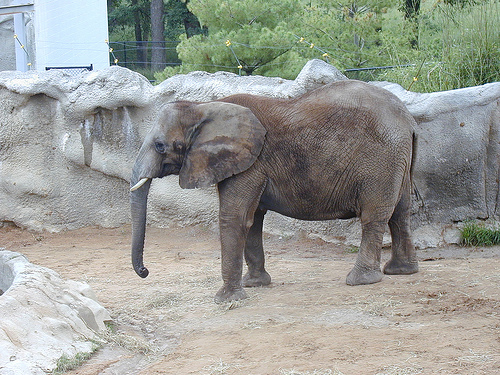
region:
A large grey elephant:
[117, 85, 427, 298]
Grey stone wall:
[0, 62, 497, 261]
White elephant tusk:
[116, 162, 161, 209]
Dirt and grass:
[30, 232, 497, 372]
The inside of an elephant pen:
[2, 65, 494, 373]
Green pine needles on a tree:
[152, 0, 339, 76]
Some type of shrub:
[385, 0, 498, 80]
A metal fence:
[346, 65, 415, 78]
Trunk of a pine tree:
[132, 0, 174, 71]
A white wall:
[20, 0, 112, 65]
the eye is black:
[149, 144, 179, 156]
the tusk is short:
[128, 176, 160, 195]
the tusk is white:
[126, 163, 153, 197]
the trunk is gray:
[125, 175, 172, 288]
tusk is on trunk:
[125, 165, 165, 277]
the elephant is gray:
[174, 102, 426, 292]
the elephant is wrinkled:
[247, 105, 392, 209]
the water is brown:
[155, 268, 485, 350]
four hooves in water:
[209, 259, 436, 316]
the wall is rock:
[2, 79, 297, 230]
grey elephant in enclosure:
[120, 80, 424, 290]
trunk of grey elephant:
[117, 155, 159, 278]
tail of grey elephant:
[401, 125, 432, 220]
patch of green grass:
[463, 225, 495, 247]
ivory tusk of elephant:
[124, 177, 152, 189]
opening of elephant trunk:
[137, 268, 152, 279]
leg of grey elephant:
[205, 227, 252, 310]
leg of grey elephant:
[382, 226, 427, 278]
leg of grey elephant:
[240, 230, 270, 290]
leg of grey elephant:
[350, 236, 395, 301]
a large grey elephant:
[128, 81, 418, 304]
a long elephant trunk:
[132, 136, 150, 278]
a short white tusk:
[129, 176, 147, 192]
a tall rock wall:
[1, 58, 498, 255]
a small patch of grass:
[464, 226, 498, 247]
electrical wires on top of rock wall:
[0, 34, 499, 86]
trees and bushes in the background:
[109, 0, 499, 92]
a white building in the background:
[0, 0, 109, 70]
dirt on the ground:
[1, 228, 498, 374]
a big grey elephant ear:
[176, 98, 266, 193]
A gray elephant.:
[125, 92, 430, 291]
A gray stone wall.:
[9, 75, 497, 245]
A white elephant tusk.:
[127, 174, 156, 196]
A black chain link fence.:
[107, 36, 189, 78]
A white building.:
[25, 2, 104, 69]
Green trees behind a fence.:
[169, 5, 485, 83]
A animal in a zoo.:
[127, 93, 438, 295]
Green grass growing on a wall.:
[451, 217, 496, 248]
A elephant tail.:
[405, 130, 431, 202]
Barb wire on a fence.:
[12, 37, 370, 72]